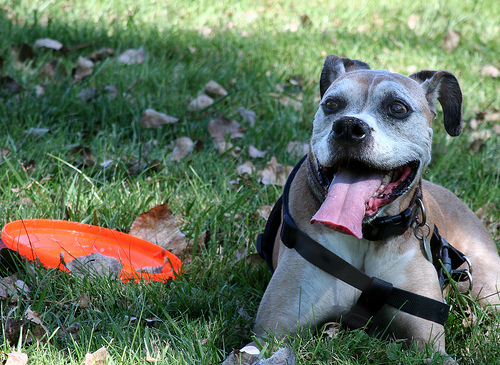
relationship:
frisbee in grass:
[1, 217, 184, 285] [2, 1, 500, 364]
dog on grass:
[240, 55, 499, 364] [2, 1, 500, 364]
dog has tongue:
[240, 55, 499, 364] [309, 170, 388, 243]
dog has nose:
[240, 55, 499, 364] [332, 114, 368, 142]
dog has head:
[240, 55, 499, 364] [310, 52, 465, 240]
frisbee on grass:
[1, 217, 184, 285] [2, 1, 500, 364]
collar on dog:
[307, 152, 426, 242] [240, 55, 499, 364]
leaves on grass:
[141, 79, 244, 167] [2, 1, 500, 364]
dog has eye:
[240, 55, 499, 364] [386, 99, 413, 115]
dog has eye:
[240, 55, 499, 364] [321, 97, 346, 113]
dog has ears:
[240, 55, 499, 364] [316, 49, 463, 138]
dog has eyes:
[240, 55, 499, 364] [321, 95, 411, 120]